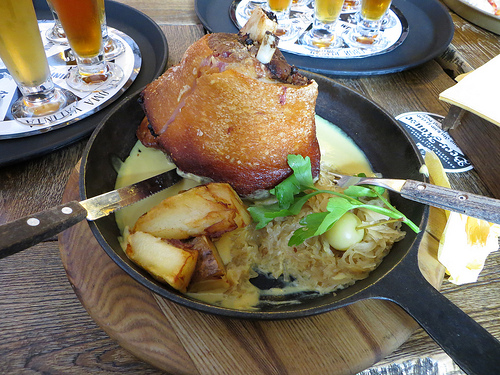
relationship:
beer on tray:
[11, 24, 139, 105] [7, 28, 135, 128]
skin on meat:
[195, 76, 254, 114] [133, 8, 323, 186]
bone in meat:
[235, 7, 284, 64] [150, 34, 323, 191]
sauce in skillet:
[131, 146, 156, 180] [62, 74, 497, 366]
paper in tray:
[45, 42, 71, 82] [1, 0, 128, 125]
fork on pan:
[314, 157, 482, 239] [60, 79, 445, 331]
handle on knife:
[1, 202, 86, 260] [1, 169, 183, 259]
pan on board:
[56, 50, 498, 373] [43, 68, 498, 367]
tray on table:
[1, 1, 169, 171] [0, 1, 497, 372]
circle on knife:
[24, 212, 49, 231] [21, 122, 195, 271]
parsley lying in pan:
[299, 174, 362, 241] [77, 62, 477, 371]